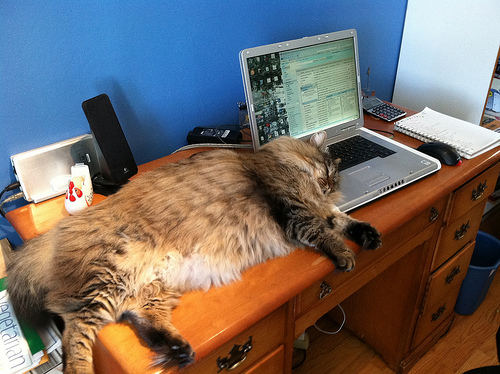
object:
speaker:
[81, 93, 138, 186]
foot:
[156, 334, 193, 366]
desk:
[1, 100, 500, 374]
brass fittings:
[215, 178, 487, 374]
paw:
[333, 250, 356, 274]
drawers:
[395, 165, 500, 372]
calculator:
[361, 96, 407, 123]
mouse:
[416, 142, 463, 167]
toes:
[146, 340, 194, 371]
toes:
[348, 220, 383, 252]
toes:
[335, 253, 357, 272]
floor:
[293, 278, 500, 374]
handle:
[214, 333, 258, 374]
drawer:
[152, 302, 293, 374]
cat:
[0, 130, 384, 374]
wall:
[0, 0, 406, 234]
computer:
[238, 27, 442, 218]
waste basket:
[451, 232, 500, 319]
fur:
[102, 146, 291, 291]